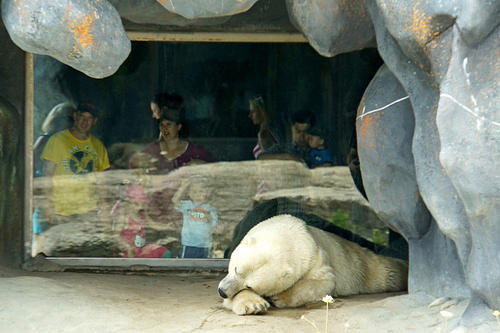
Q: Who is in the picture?
A: A group of people.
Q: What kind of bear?
A: Polar.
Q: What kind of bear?
A: Polar.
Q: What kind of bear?
A: Polar.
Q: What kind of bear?
A: Polar.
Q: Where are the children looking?
A: Cave.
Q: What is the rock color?
A: Grey.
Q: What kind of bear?
A: Polar.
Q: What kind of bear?
A: Polar.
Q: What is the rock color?
A: Grey.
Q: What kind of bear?
A: Polar.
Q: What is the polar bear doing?
A: Sleeping.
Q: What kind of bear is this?
A: A polar bear.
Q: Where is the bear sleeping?
A: In a zoo.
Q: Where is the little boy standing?
A: Behind the glass.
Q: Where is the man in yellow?
A: Behind the glass.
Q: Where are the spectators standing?
A: Behind the glass panel.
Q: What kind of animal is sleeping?
A: A bear.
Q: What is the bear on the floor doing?
A: Sleeping.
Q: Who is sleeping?
A: Polar bear.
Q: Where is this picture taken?
A: Zoo.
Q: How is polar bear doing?
A: Sleeping comfortably.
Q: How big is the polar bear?
A: Huge.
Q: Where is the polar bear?
A: Zoo.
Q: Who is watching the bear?
A: Visitors at the zoo.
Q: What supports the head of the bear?
A: Legs.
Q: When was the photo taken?
A: Daytime.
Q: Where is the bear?
A: In a zoo.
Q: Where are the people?
A: Behind the glass wall.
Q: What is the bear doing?
A: Taking a nap.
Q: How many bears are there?
A: One.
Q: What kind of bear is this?
A: Polar bear.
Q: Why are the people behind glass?
A: To observe the bear.